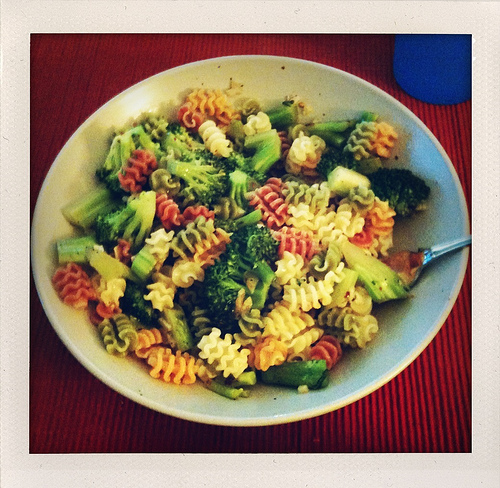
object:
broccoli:
[371, 167, 431, 218]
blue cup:
[392, 34, 471, 105]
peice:
[118, 149, 158, 195]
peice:
[29, 55, 471, 427]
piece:
[342, 121, 398, 161]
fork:
[379, 235, 472, 291]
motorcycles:
[409, 361, 451, 441]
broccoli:
[167, 148, 230, 207]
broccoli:
[212, 221, 281, 285]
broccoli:
[90, 190, 157, 254]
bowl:
[29, 54, 471, 427]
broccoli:
[261, 359, 328, 390]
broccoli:
[199, 258, 270, 331]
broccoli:
[214, 208, 263, 233]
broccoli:
[307, 121, 349, 148]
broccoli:
[95, 125, 166, 193]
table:
[31, 36, 473, 455]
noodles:
[50, 77, 398, 385]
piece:
[327, 165, 373, 198]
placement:
[31, 35, 473, 452]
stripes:
[345, 413, 405, 454]